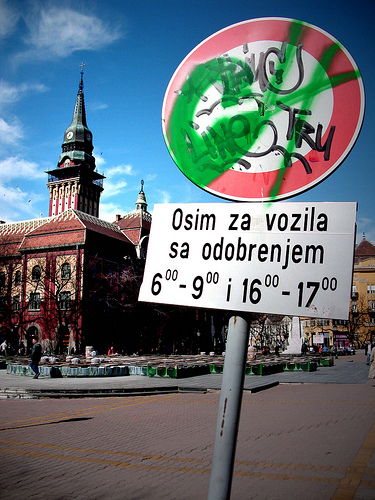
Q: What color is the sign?
A: The sign is red and white.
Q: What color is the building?
A: The building is red.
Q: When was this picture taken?
A: It was taken in the day time.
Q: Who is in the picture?
A: Multiple people are in the picture.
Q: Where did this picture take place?
A: Outside near a sign.